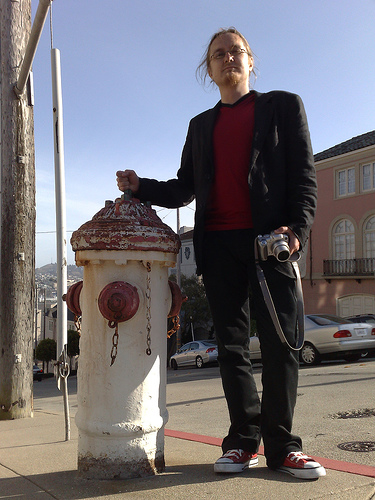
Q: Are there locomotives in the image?
A: No, there are no locomotives.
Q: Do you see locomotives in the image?
A: No, there are no locomotives.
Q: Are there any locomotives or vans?
A: No, there are no locomotives or vans.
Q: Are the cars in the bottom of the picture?
A: Yes, the cars are in the bottom of the image.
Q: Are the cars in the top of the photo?
A: No, the cars are in the bottom of the image.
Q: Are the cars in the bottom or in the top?
A: The cars are in the bottom of the image.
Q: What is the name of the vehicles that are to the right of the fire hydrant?
A: The vehicles are cars.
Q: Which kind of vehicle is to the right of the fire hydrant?
A: The vehicles are cars.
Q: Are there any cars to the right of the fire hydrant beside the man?
A: Yes, there are cars to the right of the fire hydrant.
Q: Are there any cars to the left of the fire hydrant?
A: No, the cars are to the right of the fire hydrant.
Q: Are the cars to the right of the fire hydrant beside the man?
A: Yes, the cars are to the right of the hydrant.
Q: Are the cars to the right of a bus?
A: No, the cars are to the right of the hydrant.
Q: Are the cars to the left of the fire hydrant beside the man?
A: No, the cars are to the right of the fire hydrant.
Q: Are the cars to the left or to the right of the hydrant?
A: The cars are to the right of the hydrant.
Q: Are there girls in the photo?
A: No, there are no girls.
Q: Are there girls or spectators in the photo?
A: No, there are no girls or spectators.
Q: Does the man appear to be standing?
A: Yes, the man is standing.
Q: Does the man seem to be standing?
A: Yes, the man is standing.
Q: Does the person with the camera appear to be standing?
A: Yes, the man is standing.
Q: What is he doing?
A: The man is standing.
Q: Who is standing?
A: The man is standing.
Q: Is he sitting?
A: No, the man is standing.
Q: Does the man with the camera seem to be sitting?
A: No, the man is standing.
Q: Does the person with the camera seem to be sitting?
A: No, the man is standing.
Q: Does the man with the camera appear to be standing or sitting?
A: The man is standing.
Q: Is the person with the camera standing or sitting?
A: The man is standing.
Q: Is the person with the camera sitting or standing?
A: The man is standing.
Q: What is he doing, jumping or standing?
A: The man is standing.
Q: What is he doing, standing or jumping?
A: The man is standing.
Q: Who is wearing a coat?
A: The man is wearing a coat.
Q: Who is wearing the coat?
A: The man is wearing a coat.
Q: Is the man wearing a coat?
A: Yes, the man is wearing a coat.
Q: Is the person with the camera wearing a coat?
A: Yes, the man is wearing a coat.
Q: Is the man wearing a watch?
A: No, the man is wearing a coat.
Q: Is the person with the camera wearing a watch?
A: No, the man is wearing a coat.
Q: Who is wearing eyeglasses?
A: The man is wearing eyeglasses.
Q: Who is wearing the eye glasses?
A: The man is wearing eyeglasses.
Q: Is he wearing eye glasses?
A: Yes, the man is wearing eye glasses.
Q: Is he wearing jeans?
A: No, the man is wearing eye glasses.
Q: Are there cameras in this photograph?
A: Yes, there is a camera.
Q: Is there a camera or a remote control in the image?
A: Yes, there is a camera.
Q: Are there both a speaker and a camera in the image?
A: No, there is a camera but no speakers.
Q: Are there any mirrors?
A: No, there are no mirrors.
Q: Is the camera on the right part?
A: Yes, the camera is on the right of the image.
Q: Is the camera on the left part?
A: No, the camera is on the right of the image.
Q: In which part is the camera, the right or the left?
A: The camera is on the right of the image.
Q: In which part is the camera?
A: The camera is on the right of the image.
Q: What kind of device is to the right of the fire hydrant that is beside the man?
A: The device is a camera.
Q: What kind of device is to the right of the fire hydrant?
A: The device is a camera.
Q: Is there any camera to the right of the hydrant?
A: Yes, there is a camera to the right of the hydrant.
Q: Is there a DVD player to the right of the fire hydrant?
A: No, there is a camera to the right of the fire hydrant.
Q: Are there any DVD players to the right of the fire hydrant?
A: No, there is a camera to the right of the fire hydrant.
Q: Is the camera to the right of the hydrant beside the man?
A: Yes, the camera is to the right of the fire hydrant.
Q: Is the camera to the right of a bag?
A: No, the camera is to the right of the fire hydrant.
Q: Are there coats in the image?
A: Yes, there is a coat.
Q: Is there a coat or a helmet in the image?
A: Yes, there is a coat.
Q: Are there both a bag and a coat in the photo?
A: No, there is a coat but no bags.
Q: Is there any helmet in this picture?
A: No, there are no helmets.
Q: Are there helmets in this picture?
A: No, there are no helmets.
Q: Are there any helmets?
A: No, there are no helmets.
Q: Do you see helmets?
A: No, there are no helmets.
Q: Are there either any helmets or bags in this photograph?
A: No, there are no helmets or bags.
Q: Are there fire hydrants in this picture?
A: Yes, there is a fire hydrant.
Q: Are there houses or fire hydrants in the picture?
A: Yes, there is a fire hydrant.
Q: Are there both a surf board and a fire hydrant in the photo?
A: No, there is a fire hydrant but no surfboards.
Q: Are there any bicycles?
A: No, there are no bicycles.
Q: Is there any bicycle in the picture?
A: No, there are no bicycles.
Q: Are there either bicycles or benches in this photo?
A: No, there are no bicycles or benches.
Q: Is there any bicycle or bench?
A: No, there are no bicycles or benches.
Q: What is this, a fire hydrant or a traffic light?
A: This is a fire hydrant.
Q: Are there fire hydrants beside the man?
A: Yes, there is a fire hydrant beside the man.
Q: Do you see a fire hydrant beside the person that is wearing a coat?
A: Yes, there is a fire hydrant beside the man.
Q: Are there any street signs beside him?
A: No, there is a fire hydrant beside the man.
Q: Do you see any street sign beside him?
A: No, there is a fire hydrant beside the man.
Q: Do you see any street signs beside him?
A: No, there is a fire hydrant beside the man.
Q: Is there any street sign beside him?
A: No, there is a fire hydrant beside the man.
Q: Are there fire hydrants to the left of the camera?
A: Yes, there is a fire hydrant to the left of the camera.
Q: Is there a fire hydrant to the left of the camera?
A: Yes, there is a fire hydrant to the left of the camera.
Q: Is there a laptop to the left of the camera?
A: No, there is a fire hydrant to the left of the camera.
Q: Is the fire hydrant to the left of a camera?
A: Yes, the fire hydrant is to the left of a camera.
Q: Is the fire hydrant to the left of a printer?
A: No, the fire hydrant is to the left of a camera.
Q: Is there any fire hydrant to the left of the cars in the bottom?
A: Yes, there is a fire hydrant to the left of the cars.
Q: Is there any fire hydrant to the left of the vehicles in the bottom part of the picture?
A: Yes, there is a fire hydrant to the left of the cars.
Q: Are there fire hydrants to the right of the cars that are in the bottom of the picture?
A: No, the fire hydrant is to the left of the cars.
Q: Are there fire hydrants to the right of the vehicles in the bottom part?
A: No, the fire hydrant is to the left of the cars.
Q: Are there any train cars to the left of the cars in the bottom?
A: No, there is a fire hydrant to the left of the cars.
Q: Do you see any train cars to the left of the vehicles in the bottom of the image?
A: No, there is a fire hydrant to the left of the cars.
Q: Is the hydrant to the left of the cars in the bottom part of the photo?
A: Yes, the hydrant is to the left of the cars.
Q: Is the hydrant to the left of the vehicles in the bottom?
A: Yes, the hydrant is to the left of the cars.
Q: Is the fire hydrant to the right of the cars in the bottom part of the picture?
A: No, the fire hydrant is to the left of the cars.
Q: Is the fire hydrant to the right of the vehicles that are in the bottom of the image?
A: No, the fire hydrant is to the left of the cars.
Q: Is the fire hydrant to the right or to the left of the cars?
A: The fire hydrant is to the left of the cars.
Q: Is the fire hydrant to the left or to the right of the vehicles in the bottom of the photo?
A: The fire hydrant is to the left of the cars.